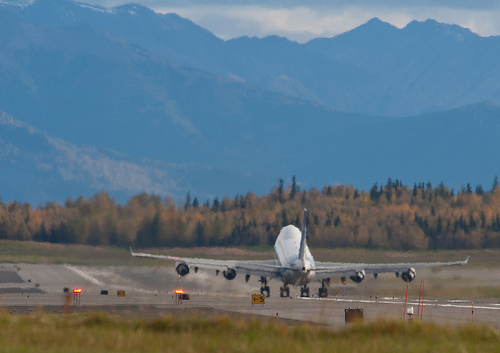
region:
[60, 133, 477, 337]
An airplane on the runway.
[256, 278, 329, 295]
The wheels of the airplane.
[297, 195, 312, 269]
Tail section of airplane.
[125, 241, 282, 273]
Left wing of airplane.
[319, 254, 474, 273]
Right wing of airplane.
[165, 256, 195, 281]
Left outside engine of airplane.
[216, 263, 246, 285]
Left inside engine of airplane.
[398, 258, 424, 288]
Right outside engine of airplane.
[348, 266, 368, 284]
Right inside engine of airplane.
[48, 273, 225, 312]
Lights on the runway.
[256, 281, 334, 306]
wheel of the aeroplane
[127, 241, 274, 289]
wings of the aeroplane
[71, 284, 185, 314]
signal lamp in the airport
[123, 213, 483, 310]
aeroplane is getting ready to take-off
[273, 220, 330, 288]
white color aeroplane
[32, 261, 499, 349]
runway of the aeroplane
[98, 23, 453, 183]
mountains with clouds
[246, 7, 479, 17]
white color clouds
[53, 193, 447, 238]
trees near the airport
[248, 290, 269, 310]
yellow color number board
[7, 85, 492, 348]
A plane is taking off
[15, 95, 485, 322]
The plane is clearing the runway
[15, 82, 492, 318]
A plane is leaving on time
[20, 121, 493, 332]
An airliner is carrying passengers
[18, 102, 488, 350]
A plane is leaving a local airport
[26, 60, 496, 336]
A plane is headed overseas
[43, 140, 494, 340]
A commercial jet has paying passengers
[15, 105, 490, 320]
A jet is leaving for Hawaii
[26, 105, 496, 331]
The jet is flying to China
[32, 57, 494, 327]
The jet has been in Japan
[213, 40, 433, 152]
this is the sky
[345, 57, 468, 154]
the sky is blue in color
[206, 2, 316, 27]
these are the clouds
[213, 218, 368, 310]
this is a jet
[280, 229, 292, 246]
the jet the jet is white in color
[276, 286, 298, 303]
this is the wheel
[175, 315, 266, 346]
this is a grass area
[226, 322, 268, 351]
the grass is green in color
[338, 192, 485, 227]
this is the forest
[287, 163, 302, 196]
this is a tree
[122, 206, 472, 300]
airplane taking off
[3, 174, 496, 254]
trees in the distance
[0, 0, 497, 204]
tall mountains in the distance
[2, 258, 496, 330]
airplane runway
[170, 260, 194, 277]
jet engine on a plane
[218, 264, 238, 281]
jet engine on a plane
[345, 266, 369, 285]
jet engine on a plane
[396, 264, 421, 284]
jet engine on a plane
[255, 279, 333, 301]
wheels on a plane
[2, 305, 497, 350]
grass in the foreground